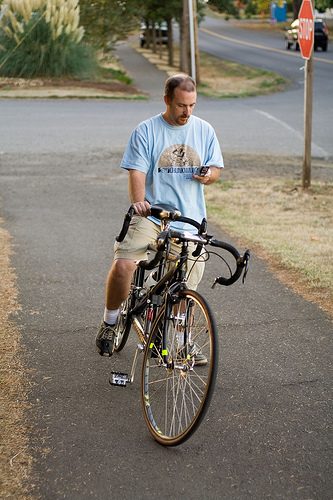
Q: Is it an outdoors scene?
A: Yes, it is outdoors.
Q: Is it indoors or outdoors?
A: It is outdoors.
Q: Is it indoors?
A: No, it is outdoors.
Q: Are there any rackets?
A: No, there are no rackets.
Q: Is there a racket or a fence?
A: No, there are no rackets or fences.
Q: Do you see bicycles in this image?
A: Yes, there is a bicycle.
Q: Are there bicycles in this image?
A: Yes, there is a bicycle.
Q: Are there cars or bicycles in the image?
A: Yes, there is a bicycle.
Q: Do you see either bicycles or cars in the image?
A: Yes, there is a bicycle.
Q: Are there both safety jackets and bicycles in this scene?
A: No, there is a bicycle but no safety jackets.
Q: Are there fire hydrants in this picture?
A: No, there are no fire hydrants.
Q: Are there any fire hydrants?
A: No, there are no fire hydrants.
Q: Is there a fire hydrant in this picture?
A: No, there are no fire hydrants.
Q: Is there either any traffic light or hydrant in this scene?
A: No, there are no fire hydrants or traffic lights.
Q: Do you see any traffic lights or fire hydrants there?
A: No, there are no fire hydrants or traffic lights.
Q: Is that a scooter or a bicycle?
A: That is a bicycle.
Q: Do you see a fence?
A: No, there are no fences.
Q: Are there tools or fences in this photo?
A: No, there are no fences or tools.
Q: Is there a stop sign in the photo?
A: Yes, there is a stop sign.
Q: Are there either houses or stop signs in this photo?
A: Yes, there is a stop sign.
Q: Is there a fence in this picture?
A: No, there are no fences.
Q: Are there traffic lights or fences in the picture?
A: No, there are no fences or traffic lights.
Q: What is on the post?
A: The stop sign is on the post.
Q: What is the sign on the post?
A: The sign is a stop sign.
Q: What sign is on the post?
A: The sign is a stop sign.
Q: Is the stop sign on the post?
A: Yes, the stop sign is on the post.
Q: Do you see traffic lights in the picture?
A: No, there are no traffic lights.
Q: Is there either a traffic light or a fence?
A: No, there are no traffic lights or fences.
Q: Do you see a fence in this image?
A: No, there are no fences.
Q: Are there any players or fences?
A: No, there are no fences or players.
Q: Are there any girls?
A: No, there are no girls.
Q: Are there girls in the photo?
A: No, there are no girls.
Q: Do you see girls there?
A: No, there are no girls.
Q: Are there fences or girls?
A: No, there are no girls or fences.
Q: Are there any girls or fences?
A: No, there are no girls or fences.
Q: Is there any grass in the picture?
A: Yes, there is grass.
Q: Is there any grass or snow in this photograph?
A: Yes, there is grass.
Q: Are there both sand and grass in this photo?
A: No, there is grass but no sand.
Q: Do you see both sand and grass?
A: No, there is grass but no sand.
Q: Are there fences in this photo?
A: No, there are no fences.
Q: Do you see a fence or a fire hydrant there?
A: No, there are no fences or fire hydrants.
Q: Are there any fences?
A: No, there are no fences.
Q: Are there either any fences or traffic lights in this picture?
A: No, there are no fences or traffic lights.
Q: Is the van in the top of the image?
A: Yes, the van is in the top of the image.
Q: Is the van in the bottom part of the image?
A: No, the van is in the top of the image.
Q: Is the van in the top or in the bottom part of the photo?
A: The van is in the top of the image.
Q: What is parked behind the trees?
A: The van is parked behind the trees.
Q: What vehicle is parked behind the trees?
A: The vehicle is a van.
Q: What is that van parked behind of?
A: The van is parked behind the trees.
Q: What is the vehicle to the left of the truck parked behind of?
A: The van is parked behind the trees.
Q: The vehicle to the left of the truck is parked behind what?
A: The van is parked behind the trees.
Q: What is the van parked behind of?
A: The van is parked behind the trees.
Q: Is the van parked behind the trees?
A: Yes, the van is parked behind the trees.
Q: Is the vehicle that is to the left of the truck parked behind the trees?
A: Yes, the van is parked behind the trees.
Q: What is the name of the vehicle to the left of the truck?
A: The vehicle is a van.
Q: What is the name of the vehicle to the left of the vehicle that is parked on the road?
A: The vehicle is a van.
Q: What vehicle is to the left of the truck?
A: The vehicle is a van.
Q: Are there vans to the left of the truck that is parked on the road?
A: Yes, there is a van to the left of the truck.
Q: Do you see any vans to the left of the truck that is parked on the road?
A: Yes, there is a van to the left of the truck.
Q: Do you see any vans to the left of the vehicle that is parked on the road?
A: Yes, there is a van to the left of the truck.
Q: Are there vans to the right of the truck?
A: No, the van is to the left of the truck.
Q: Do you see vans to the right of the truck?
A: No, the van is to the left of the truck.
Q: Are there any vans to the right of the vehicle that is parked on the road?
A: No, the van is to the left of the truck.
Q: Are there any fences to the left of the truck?
A: No, there is a van to the left of the truck.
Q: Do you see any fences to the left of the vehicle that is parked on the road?
A: No, there is a van to the left of the truck.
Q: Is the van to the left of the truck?
A: Yes, the van is to the left of the truck.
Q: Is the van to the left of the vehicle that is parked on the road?
A: Yes, the van is to the left of the truck.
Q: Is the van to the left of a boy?
A: No, the van is to the left of the truck.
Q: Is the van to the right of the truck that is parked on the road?
A: No, the van is to the left of the truck.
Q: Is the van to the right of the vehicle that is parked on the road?
A: No, the van is to the left of the truck.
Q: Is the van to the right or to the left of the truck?
A: The van is to the left of the truck.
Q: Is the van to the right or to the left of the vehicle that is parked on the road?
A: The van is to the left of the truck.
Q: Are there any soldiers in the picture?
A: No, there are no soldiers.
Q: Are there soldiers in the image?
A: No, there are no soldiers.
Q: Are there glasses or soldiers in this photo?
A: No, there are no soldiers or glasses.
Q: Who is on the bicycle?
A: The guy is on the bicycle.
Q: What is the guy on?
A: The guy is on the bicycle.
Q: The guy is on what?
A: The guy is on the bicycle.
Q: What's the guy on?
A: The guy is on the bicycle.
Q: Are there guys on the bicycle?
A: Yes, there is a guy on the bicycle.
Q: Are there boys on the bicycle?
A: No, there is a guy on the bicycle.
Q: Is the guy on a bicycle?
A: Yes, the guy is on a bicycle.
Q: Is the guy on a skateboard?
A: No, the guy is on a bicycle.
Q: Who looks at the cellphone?
A: The guy looks at the cellphone.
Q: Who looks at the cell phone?
A: The guy looks at the cellphone.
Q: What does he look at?
A: The guy looks at the cell phone.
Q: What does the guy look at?
A: The guy looks at the cell phone.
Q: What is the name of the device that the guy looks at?
A: The device is a cell phone.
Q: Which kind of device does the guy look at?
A: The guy looks at the mobile phone.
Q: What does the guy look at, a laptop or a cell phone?
A: The guy looks at a cell phone.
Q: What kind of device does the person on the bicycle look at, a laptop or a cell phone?
A: The guy looks at a cell phone.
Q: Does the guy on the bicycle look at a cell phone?
A: Yes, the guy looks at a cell phone.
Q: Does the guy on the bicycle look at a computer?
A: No, the guy looks at a cell phone.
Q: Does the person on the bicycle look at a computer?
A: No, the guy looks at a cell phone.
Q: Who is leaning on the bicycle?
A: The guy is leaning on the bicycle.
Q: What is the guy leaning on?
A: The guy is leaning on the bicycle.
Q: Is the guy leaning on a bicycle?
A: Yes, the guy is leaning on a bicycle.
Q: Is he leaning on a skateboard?
A: No, the guy is leaning on a bicycle.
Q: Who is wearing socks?
A: The guy is wearing socks.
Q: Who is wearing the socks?
A: The guy is wearing socks.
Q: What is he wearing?
A: The guy is wearing socks.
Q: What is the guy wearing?
A: The guy is wearing socks.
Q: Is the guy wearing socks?
A: Yes, the guy is wearing socks.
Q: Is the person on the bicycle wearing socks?
A: Yes, the guy is wearing socks.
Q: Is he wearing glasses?
A: No, the guy is wearing socks.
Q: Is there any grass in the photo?
A: Yes, there is grass.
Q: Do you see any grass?
A: Yes, there is grass.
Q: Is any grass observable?
A: Yes, there is grass.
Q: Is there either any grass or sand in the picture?
A: Yes, there is grass.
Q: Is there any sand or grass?
A: Yes, there is grass.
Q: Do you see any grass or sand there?
A: Yes, there is grass.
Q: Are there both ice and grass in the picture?
A: No, there is grass but no ice.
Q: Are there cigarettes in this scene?
A: No, there are no cigarettes.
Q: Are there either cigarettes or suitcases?
A: No, there are no cigarettes or suitcases.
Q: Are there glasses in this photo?
A: No, there are no glasses.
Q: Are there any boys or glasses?
A: No, there are no glasses or boys.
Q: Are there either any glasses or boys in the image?
A: No, there are no glasses or boys.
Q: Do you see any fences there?
A: No, there are no fences.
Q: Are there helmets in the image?
A: No, there are no helmets.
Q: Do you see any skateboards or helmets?
A: No, there are no helmets or skateboards.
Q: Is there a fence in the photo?
A: No, there are no fences.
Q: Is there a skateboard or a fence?
A: No, there are no fences or skateboards.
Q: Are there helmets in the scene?
A: No, there are no helmets.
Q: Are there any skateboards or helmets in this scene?
A: No, there are no helmets or skateboards.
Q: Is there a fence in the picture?
A: No, there are no fences.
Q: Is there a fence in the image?
A: No, there are no fences.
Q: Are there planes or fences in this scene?
A: No, there are no fences or planes.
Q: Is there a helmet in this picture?
A: No, there are no helmets.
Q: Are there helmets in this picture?
A: No, there are no helmets.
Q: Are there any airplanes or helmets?
A: No, there are no helmets or airplanes.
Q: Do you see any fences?
A: No, there are no fences.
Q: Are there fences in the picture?
A: No, there are no fences.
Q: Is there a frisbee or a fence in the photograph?
A: No, there are no fences or frisbees.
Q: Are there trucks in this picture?
A: Yes, there is a truck.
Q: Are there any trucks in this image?
A: Yes, there is a truck.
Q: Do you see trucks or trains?
A: Yes, there is a truck.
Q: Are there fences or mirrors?
A: No, there are no fences or mirrors.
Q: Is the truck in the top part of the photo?
A: Yes, the truck is in the top of the image.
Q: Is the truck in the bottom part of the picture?
A: No, the truck is in the top of the image.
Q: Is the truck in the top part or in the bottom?
A: The truck is in the top of the image.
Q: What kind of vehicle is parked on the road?
A: The vehicle is a truck.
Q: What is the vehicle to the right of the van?
A: The vehicle is a truck.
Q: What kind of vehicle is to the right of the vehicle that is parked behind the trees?
A: The vehicle is a truck.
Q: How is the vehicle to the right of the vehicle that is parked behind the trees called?
A: The vehicle is a truck.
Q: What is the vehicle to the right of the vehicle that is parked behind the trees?
A: The vehicle is a truck.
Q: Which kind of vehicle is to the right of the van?
A: The vehicle is a truck.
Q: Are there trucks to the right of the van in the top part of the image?
A: Yes, there is a truck to the right of the van.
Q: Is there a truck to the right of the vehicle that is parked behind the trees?
A: Yes, there is a truck to the right of the van.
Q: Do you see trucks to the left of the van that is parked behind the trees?
A: No, the truck is to the right of the van.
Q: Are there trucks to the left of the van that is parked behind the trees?
A: No, the truck is to the right of the van.